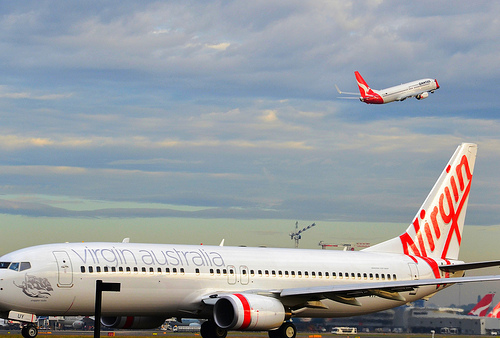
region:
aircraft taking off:
[342, 65, 440, 105]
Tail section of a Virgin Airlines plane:
[400, 137, 495, 280]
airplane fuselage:
[2, 240, 462, 315]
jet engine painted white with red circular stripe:
[202, 292, 284, 330]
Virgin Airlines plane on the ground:
[10, 142, 495, 329]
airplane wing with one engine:
[196, 271, 496, 329]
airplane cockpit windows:
[1, 258, 27, 268]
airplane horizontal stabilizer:
[441, 255, 496, 272]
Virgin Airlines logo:
[390, 136, 473, 296]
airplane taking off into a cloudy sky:
[4, 3, 497, 144]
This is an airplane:
[327, 66, 447, 115]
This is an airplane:
[0, 141, 499, 329]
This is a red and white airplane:
[328, 59, 447, 120]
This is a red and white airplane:
[0, 142, 495, 333]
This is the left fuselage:
[199, 279, 299, 334]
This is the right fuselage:
[91, 298, 188, 333]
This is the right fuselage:
[413, 89, 435, 107]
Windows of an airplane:
[75, 261, 401, 286]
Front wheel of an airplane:
[24, 314, 41, 337]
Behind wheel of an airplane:
[276, 315, 307, 336]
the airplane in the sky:
[333, 69, 441, 104]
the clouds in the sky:
[0, 0, 499, 227]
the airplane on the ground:
[0, 140, 499, 335]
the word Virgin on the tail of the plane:
[399, 154, 471, 277]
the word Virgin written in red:
[400, 154, 472, 285]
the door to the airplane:
[53, 250, 73, 284]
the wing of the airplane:
[202, 273, 499, 314]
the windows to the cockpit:
[0, 260, 31, 271]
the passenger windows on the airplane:
[79, 265, 396, 280]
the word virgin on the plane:
[71, 246, 138, 267]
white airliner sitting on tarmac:
[11, 205, 445, 333]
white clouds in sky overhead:
[15, 13, 482, 247]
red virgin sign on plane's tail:
[387, 157, 482, 258]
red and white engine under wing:
[211, 295, 287, 332]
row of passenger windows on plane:
[82, 254, 389, 277]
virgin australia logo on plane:
[65, 240, 235, 275]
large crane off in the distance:
[291, 217, 320, 240]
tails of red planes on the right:
[468, 295, 493, 310]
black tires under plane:
[270, 322, 293, 334]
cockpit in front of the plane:
[9, 251, 31, 270]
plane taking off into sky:
[332, 69, 441, 105]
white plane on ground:
[0, 140, 499, 337]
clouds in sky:
[0, 0, 498, 227]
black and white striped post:
[287, 220, 317, 241]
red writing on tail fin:
[397, 153, 476, 284]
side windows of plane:
[78, 264, 398, 282]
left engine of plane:
[212, 293, 287, 332]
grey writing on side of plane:
[70, 245, 226, 270]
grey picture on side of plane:
[10, 273, 53, 303]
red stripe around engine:
[228, 291, 254, 331]